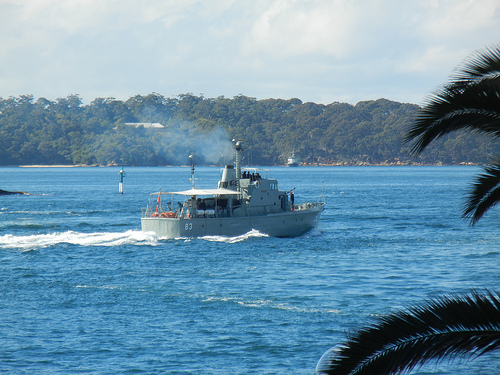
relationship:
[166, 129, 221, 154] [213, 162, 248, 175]
smoke from stack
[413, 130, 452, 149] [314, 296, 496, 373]
leaves of tree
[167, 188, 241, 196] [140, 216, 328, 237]
overhang on boat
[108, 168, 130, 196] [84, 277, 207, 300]
buoy in water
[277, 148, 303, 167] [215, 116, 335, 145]
house surrounded by trees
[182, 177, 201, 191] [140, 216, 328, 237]
flag on boat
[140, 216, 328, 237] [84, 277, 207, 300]
boat in water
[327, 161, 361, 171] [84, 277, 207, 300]
shoreline of water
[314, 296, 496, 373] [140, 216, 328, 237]
tree next to boat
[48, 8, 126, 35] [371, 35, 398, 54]
clouds in sky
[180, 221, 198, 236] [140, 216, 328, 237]
83 on boat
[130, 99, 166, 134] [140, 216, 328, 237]
steam coming out of boat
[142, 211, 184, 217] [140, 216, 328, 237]
life jackets on boat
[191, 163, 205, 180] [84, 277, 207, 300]
pole in water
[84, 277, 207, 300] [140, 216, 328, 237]
water by boat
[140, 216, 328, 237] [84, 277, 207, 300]
boat on water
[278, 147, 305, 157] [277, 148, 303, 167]
roof of house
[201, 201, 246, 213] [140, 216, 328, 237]
bridge of boat